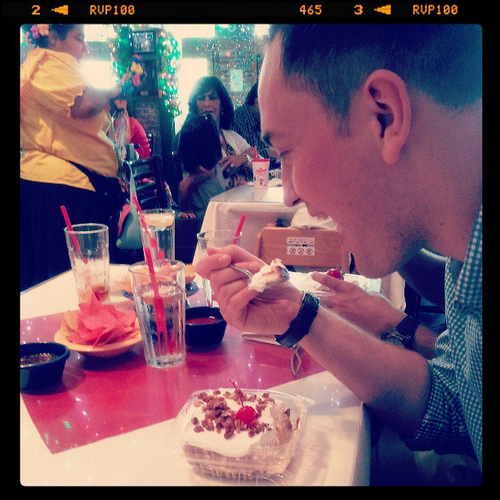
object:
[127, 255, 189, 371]
glass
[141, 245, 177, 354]
straw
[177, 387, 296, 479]
dessert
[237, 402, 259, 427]
cherry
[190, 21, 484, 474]
man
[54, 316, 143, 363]
dish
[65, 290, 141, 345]
chips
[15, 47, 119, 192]
blouse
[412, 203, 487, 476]
shirt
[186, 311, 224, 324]
salsa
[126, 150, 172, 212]
chair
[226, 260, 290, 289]
fork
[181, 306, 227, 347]
bowl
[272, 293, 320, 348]
watch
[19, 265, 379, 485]
table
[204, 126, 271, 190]
t-shirt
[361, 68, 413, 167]
ear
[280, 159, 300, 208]
nose